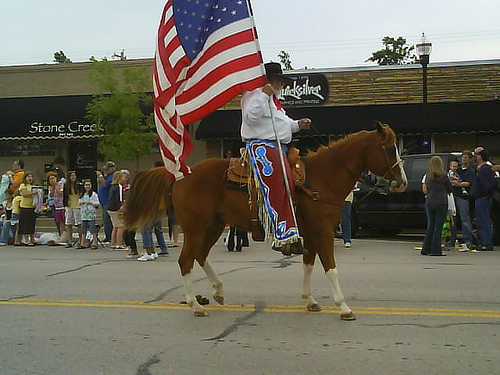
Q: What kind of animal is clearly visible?
A: Horse.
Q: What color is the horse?
A: Brown.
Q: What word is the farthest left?
A: Stone.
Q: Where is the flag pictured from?
A: America.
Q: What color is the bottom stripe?
A: Red.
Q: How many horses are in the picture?
A: 1.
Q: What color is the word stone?
A: White.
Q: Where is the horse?
A: In the street.